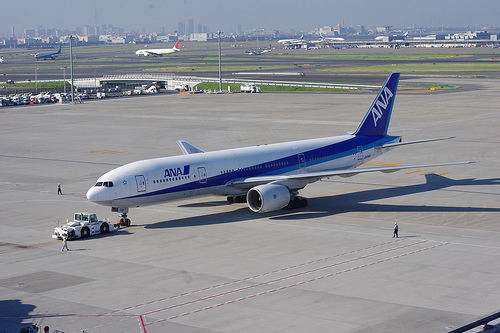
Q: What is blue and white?
A: The plane.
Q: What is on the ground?
A: Red lines.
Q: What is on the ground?
A: Shadow of the plane.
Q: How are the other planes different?
A: Different colors.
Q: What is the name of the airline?
A: ANA.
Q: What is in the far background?
A: A city.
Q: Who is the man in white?
A: Airport employee.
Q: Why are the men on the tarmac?
A: Maintaining the plane.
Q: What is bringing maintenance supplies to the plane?
A: A white truck.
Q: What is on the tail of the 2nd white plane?
A: Red paint.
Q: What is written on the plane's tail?
A: ANA.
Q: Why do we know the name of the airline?
A: It is written on the plane.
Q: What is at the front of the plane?
A: A truck.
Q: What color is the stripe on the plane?
A: Blue.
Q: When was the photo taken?
A: During the daytime.